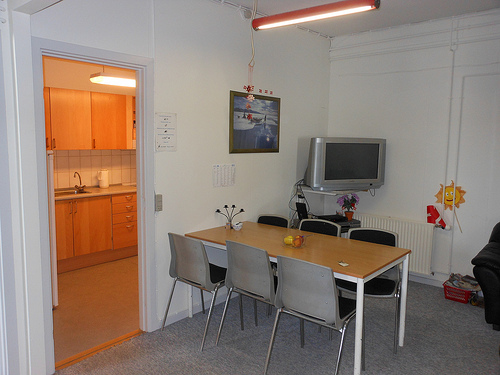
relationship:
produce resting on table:
[282, 233, 304, 244] [190, 219, 418, 371]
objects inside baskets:
[450, 270, 480, 290] [442, 276, 474, 300]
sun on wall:
[430, 183, 470, 212] [333, 26, 484, 273]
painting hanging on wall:
[230, 88, 282, 155] [153, 10, 365, 327]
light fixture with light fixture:
[248, 6, 388, 32] [251, 4, 379, 32]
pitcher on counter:
[94, 167, 108, 188] [59, 182, 131, 192]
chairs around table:
[167, 236, 348, 358] [190, 219, 418, 371]